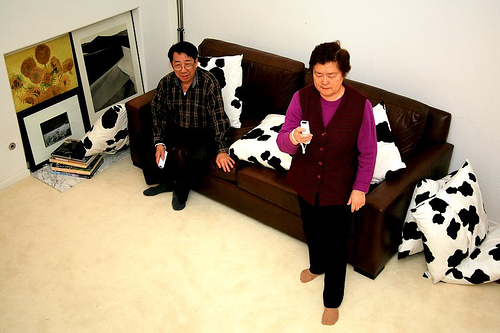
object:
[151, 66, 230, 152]
plaid shirt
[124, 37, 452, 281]
couch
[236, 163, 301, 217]
cushion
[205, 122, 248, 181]
cushion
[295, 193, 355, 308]
pants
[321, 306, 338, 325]
feet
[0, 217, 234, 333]
ground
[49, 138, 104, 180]
books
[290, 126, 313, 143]
hand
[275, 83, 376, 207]
top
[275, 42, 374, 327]
man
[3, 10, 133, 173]
black frame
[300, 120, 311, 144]
cellphone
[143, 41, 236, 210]
man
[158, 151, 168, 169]
controller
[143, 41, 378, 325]
two people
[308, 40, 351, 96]
head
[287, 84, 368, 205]
shirt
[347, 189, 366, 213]
hand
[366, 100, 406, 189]
pillow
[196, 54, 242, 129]
pillow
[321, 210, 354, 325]
leg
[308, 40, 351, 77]
hair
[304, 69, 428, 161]
couch cushion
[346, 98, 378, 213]
arm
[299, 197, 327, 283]
leg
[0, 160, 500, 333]
floor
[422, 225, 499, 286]
cow pillows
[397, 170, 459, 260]
cow pillows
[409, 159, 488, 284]
cow pillows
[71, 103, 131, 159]
cow pillows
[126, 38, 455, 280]
sofa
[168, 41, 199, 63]
hair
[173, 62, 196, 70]
glasses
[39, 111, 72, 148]
photo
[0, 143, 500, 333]
carpet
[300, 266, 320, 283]
foot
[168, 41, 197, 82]
head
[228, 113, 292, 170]
cushion